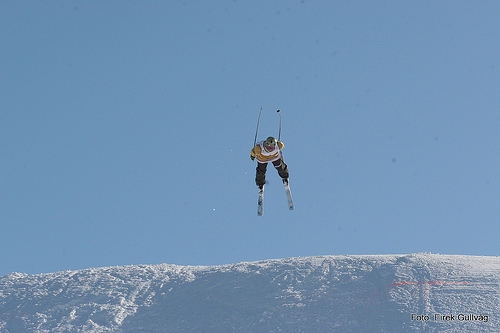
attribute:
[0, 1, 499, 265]
sky — blue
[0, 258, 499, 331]
snow — white, shining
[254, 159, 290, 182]
pants — black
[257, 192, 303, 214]
skis — white